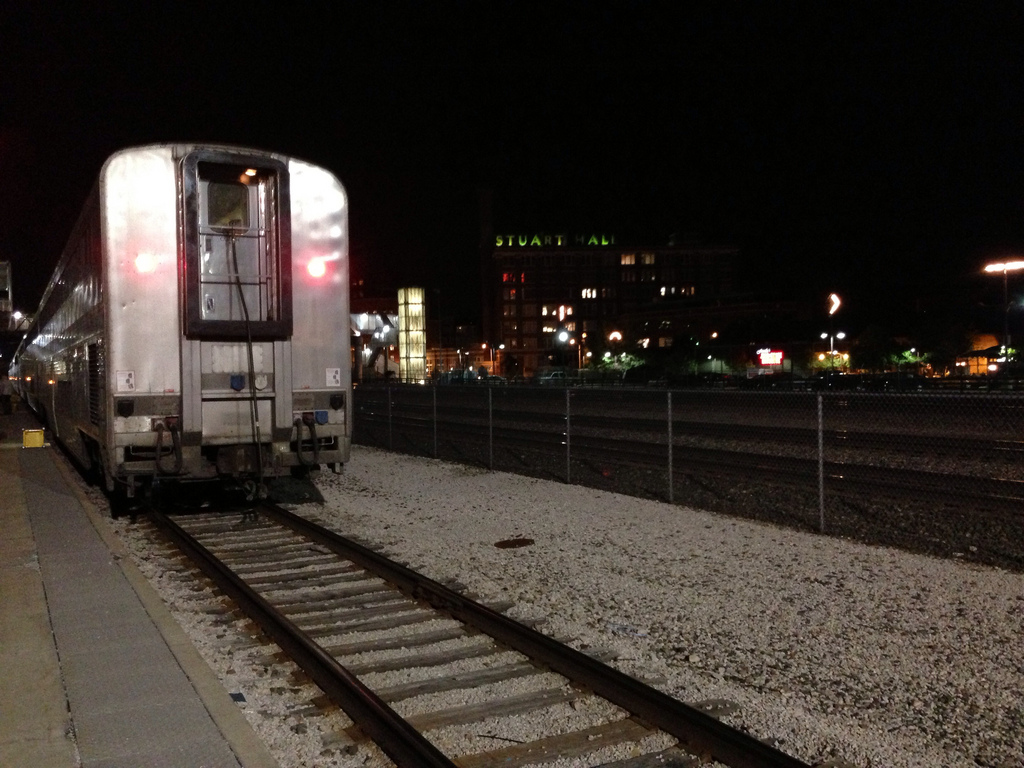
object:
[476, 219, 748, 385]
hotel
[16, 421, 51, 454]
stool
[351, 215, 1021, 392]
commercial district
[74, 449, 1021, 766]
gravel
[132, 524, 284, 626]
concrete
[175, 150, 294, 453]
back door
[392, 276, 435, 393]
light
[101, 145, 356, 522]
train back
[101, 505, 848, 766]
train tracks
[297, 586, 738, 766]
rocks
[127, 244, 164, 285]
red light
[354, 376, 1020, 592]
fence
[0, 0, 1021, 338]
sky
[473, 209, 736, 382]
building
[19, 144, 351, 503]
silver train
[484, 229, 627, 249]
letter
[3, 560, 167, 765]
floor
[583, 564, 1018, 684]
land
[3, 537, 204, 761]
walkway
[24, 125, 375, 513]
train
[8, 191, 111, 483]
side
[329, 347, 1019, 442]
top